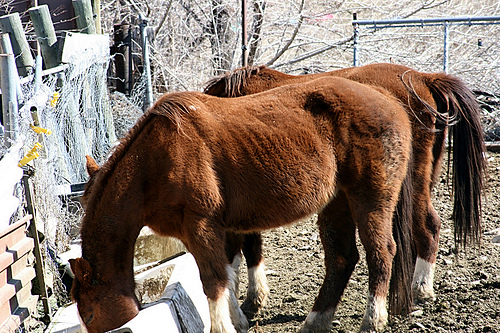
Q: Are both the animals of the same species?
A: Yes, all the animals are horses.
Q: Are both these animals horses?
A: Yes, all the animals are horses.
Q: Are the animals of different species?
A: No, all the animals are horses.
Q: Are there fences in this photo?
A: Yes, there is a fence.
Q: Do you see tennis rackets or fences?
A: Yes, there is a fence.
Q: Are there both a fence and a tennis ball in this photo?
A: No, there is a fence but no tennis balls.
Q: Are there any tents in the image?
A: No, there are no tents.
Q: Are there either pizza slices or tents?
A: No, there are no tents or pizza slices.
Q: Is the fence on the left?
A: Yes, the fence is on the left of the image.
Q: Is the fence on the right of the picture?
A: No, the fence is on the left of the image.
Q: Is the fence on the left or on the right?
A: The fence is on the left of the image.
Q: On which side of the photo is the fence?
A: The fence is on the left of the image.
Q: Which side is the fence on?
A: The fence is on the left of the image.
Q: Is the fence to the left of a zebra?
A: No, the fence is to the left of the horse.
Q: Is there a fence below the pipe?
A: Yes, there is a fence below the pipe.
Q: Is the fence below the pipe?
A: Yes, the fence is below the pipe.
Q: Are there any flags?
A: No, there are no flags.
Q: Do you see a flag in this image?
A: No, there are no flags.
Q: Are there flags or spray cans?
A: No, there are no flags or spray cans.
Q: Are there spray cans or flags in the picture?
A: No, there are no flags or spray cans.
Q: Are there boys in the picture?
A: No, there are no boys.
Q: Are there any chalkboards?
A: No, there are no chalkboards.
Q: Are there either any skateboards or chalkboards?
A: No, there are no chalkboards or skateboards.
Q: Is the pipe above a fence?
A: Yes, the pipe is above a fence.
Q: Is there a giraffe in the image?
A: No, there are no giraffes.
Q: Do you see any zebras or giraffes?
A: No, there are no giraffes or zebras.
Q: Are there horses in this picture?
A: Yes, there is a horse.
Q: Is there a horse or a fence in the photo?
A: Yes, there is a horse.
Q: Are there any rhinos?
A: No, there are no rhinos.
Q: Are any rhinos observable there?
A: No, there are no rhinos.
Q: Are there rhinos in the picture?
A: No, there are no rhinos.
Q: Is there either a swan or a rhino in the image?
A: No, there are no rhinos or swans.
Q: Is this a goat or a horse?
A: This is a horse.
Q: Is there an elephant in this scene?
A: No, there are no elephants.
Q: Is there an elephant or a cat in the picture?
A: No, there are no elephants or cats.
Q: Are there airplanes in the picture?
A: No, there are no airplanes.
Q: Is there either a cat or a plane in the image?
A: No, there are no airplanes or cats.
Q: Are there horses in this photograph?
A: Yes, there is a horse.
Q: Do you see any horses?
A: Yes, there is a horse.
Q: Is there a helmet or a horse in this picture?
A: Yes, there is a horse.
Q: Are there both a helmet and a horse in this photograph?
A: No, there is a horse but no helmets.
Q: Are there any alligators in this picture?
A: No, there are no alligators.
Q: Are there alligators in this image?
A: No, there are no alligators.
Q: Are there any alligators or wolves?
A: No, there are no alligators or wolves.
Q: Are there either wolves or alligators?
A: No, there are no alligators or wolves.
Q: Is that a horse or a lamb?
A: That is a horse.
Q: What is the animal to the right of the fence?
A: The animal is a horse.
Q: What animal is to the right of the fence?
A: The animal is a horse.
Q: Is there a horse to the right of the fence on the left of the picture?
A: Yes, there is a horse to the right of the fence.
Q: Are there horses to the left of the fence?
A: No, the horse is to the right of the fence.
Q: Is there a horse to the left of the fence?
A: No, the horse is to the right of the fence.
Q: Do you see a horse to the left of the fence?
A: No, the horse is to the right of the fence.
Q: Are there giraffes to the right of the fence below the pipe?
A: No, there is a horse to the right of the fence.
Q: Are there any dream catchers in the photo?
A: No, there are no dream catchers.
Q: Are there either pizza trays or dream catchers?
A: No, there are no dream catchers or pizza trays.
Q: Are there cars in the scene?
A: No, there are no cars.